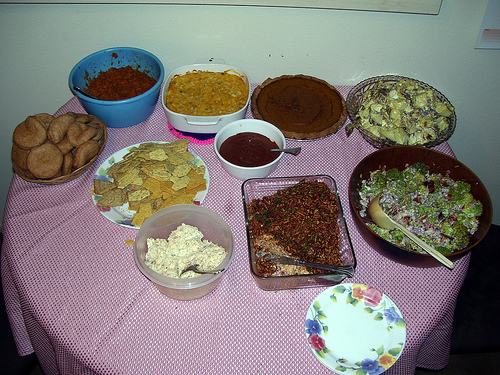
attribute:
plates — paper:
[302, 279, 412, 373]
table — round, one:
[3, 86, 473, 372]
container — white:
[159, 61, 249, 135]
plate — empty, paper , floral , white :
[300, 283, 410, 373]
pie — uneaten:
[248, 74, 348, 143]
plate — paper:
[305, 276, 407, 374]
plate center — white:
[327, 303, 377, 352]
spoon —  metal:
[255, 245, 356, 275]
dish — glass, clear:
[239, 172, 360, 293]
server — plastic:
[365, 193, 460, 271]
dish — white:
[157, 62, 251, 139]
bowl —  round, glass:
[347, 75, 460, 154]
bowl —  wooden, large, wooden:
[343, 136, 491, 266]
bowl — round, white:
[211, 113, 289, 178]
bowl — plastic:
[132, 198, 235, 306]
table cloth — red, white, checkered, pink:
[0, 73, 471, 374]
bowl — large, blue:
[65, 47, 165, 130]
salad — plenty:
[357, 163, 481, 260]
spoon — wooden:
[368, 195, 454, 269]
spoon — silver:
[271, 140, 302, 158]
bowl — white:
[212, 120, 289, 183]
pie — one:
[252, 70, 348, 142]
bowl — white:
[213, 120, 286, 178]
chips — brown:
[85, 133, 212, 214]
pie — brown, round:
[249, 69, 357, 141]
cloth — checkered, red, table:
[16, 77, 444, 373]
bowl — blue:
[66, 36, 166, 133]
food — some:
[49, 47, 471, 277]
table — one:
[13, 65, 476, 365]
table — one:
[14, 76, 498, 373]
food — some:
[360, 152, 495, 252]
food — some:
[352, 77, 452, 127]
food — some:
[178, 60, 235, 111]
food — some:
[164, 65, 277, 133]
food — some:
[96, 137, 199, 212]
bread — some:
[11, 104, 97, 174]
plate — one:
[311, 278, 405, 368]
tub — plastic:
[133, 203, 235, 301]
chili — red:
[79, 63, 158, 100]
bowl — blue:
[66, 45, 168, 126]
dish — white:
[159, 64, 249, 130]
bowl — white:
[130, 205, 236, 300]